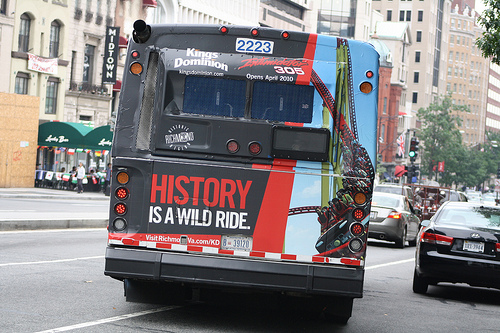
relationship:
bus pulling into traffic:
[103, 18, 380, 323] [379, 180, 485, 261]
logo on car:
[165, 42, 232, 77] [95, 8, 391, 331]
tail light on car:
[386, 209, 408, 219] [363, 186, 419, 247]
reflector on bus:
[115, 169, 138, 181] [109, 15, 379, 325]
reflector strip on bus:
[120, 233, 360, 280] [109, 15, 379, 325]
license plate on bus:
[216, 229, 253, 255] [109, 15, 379, 325]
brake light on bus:
[352, 206, 367, 219] [109, 15, 379, 325]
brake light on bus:
[349, 221, 364, 237] [109, 15, 379, 325]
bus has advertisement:
[109, 15, 379, 325] [142, 46, 370, 236]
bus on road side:
[109, 15, 379, 325] [56, 263, 498, 332]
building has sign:
[3, 0, 126, 139] [105, 24, 116, 82]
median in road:
[15, 196, 86, 246] [21, 211, 494, 331]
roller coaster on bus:
[317, 20, 375, 265] [109, 15, 379, 325]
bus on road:
[103, 18, 380, 323] [0, 227, 499, 331]